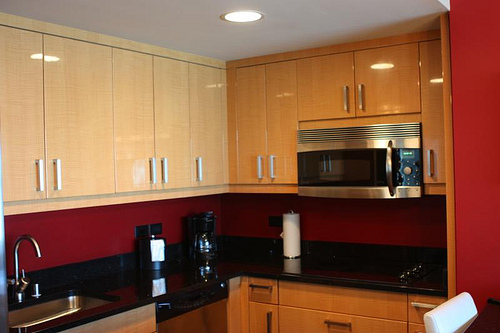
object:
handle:
[149, 157, 157, 184]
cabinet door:
[112, 46, 156, 192]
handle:
[195, 157, 203, 181]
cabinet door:
[188, 63, 224, 187]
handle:
[53, 158, 62, 190]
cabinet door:
[43, 32, 115, 201]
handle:
[162, 157, 169, 183]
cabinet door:
[153, 52, 193, 193]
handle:
[34, 159, 44, 192]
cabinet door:
[0, 25, 45, 202]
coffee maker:
[179, 211, 219, 264]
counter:
[7, 234, 446, 333]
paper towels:
[280, 212, 302, 257]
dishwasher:
[154, 278, 228, 331]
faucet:
[14, 234, 42, 303]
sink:
[0, 293, 112, 333]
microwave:
[294, 121, 422, 200]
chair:
[422, 291, 482, 331]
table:
[461, 312, 497, 332]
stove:
[281, 252, 439, 284]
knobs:
[399, 263, 424, 285]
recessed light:
[222, 10, 261, 23]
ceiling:
[0, 0, 449, 61]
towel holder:
[283, 209, 302, 259]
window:
[318, 155, 371, 182]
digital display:
[402, 151, 414, 157]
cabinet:
[112, 47, 191, 196]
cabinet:
[1, 25, 116, 205]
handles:
[269, 155, 275, 179]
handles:
[256, 156, 264, 179]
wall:
[4, 191, 445, 281]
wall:
[448, 0, 499, 316]